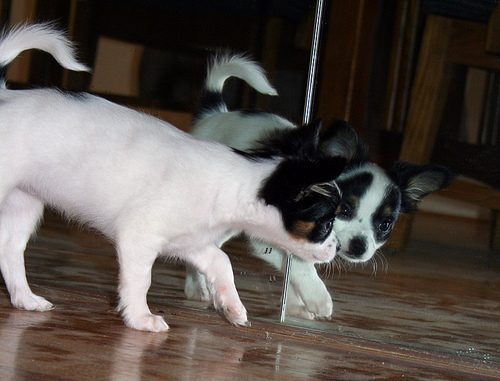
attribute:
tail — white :
[1, 23, 91, 118]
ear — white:
[301, 120, 356, 165]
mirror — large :
[7, 0, 494, 350]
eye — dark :
[320, 214, 340, 235]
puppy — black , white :
[162, 56, 429, 311]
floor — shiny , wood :
[359, 279, 494, 369]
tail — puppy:
[201, 45, 279, 115]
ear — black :
[401, 163, 459, 217]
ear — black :
[321, 115, 366, 166]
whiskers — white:
[366, 247, 391, 281]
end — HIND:
[2, 22, 72, 232]